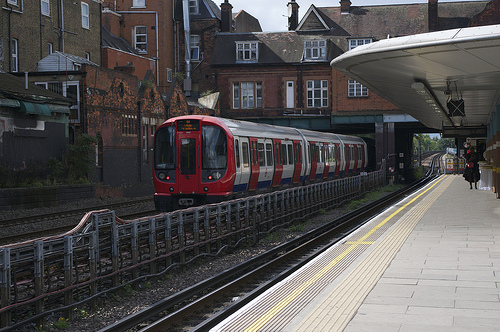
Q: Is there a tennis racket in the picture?
A: No, there are no rackets.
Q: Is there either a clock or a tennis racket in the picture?
A: No, there are no rackets or clocks.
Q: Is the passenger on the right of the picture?
A: Yes, the passenger is on the right of the image.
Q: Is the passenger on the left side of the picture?
A: No, the passenger is on the right of the image.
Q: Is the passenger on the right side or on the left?
A: The passenger is on the right of the image.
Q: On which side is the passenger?
A: The passenger is on the right of the image.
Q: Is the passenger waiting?
A: Yes, the passenger is waiting.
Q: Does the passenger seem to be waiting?
A: Yes, the passenger is waiting.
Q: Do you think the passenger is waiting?
A: Yes, the passenger is waiting.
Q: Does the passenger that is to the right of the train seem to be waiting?
A: Yes, the passenger is waiting.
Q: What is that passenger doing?
A: The passenger is waiting.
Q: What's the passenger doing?
A: The passenger is waiting.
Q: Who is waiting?
A: The passenger is waiting.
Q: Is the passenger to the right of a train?
A: Yes, the passenger is to the right of a train.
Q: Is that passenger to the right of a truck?
A: No, the passenger is to the right of a train.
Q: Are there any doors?
A: Yes, there is a door.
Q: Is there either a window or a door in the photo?
A: Yes, there is a door.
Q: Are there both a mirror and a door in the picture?
A: No, there is a door but no mirrors.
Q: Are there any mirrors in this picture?
A: No, there are no mirrors.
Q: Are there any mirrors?
A: No, there are no mirrors.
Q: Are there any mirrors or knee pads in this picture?
A: No, there are no mirrors or knee pads.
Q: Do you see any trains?
A: Yes, there is a train.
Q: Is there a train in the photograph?
A: Yes, there is a train.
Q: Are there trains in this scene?
A: Yes, there is a train.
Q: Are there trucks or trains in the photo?
A: Yes, there is a train.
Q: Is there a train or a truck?
A: Yes, there is a train.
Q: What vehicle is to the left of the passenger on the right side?
A: The vehicle is a train.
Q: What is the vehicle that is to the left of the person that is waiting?
A: The vehicle is a train.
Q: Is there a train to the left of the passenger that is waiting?
A: Yes, there is a train to the left of the passenger.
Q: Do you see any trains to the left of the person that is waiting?
A: Yes, there is a train to the left of the passenger.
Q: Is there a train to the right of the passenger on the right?
A: No, the train is to the left of the passenger.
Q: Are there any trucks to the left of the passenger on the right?
A: No, there is a train to the left of the passenger.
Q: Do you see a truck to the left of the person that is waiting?
A: No, there is a train to the left of the passenger.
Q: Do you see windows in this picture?
A: Yes, there is a window.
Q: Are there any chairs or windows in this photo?
A: Yes, there is a window.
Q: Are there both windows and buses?
A: No, there is a window but no buses.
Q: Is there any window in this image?
A: Yes, there is a window.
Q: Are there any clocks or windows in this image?
A: Yes, there is a window.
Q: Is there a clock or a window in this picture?
A: Yes, there is a window.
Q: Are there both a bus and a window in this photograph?
A: No, there is a window but no buses.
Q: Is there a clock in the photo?
A: No, there are no clocks.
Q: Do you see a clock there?
A: No, there are no clocks.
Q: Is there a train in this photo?
A: Yes, there is a train.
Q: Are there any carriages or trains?
A: Yes, there is a train.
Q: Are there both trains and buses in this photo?
A: No, there is a train but no buses.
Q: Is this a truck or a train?
A: This is a train.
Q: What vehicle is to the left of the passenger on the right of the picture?
A: The vehicle is a train.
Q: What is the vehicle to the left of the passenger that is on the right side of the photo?
A: The vehicle is a train.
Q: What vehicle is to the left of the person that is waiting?
A: The vehicle is a train.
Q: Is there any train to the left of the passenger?
A: Yes, there is a train to the left of the passenger.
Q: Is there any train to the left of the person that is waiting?
A: Yes, there is a train to the left of the passenger.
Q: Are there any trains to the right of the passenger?
A: No, the train is to the left of the passenger.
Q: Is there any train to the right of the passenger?
A: No, the train is to the left of the passenger.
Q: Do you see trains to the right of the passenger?
A: No, the train is to the left of the passenger.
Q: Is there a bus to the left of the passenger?
A: No, there is a train to the left of the passenger.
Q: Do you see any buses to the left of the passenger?
A: No, there is a train to the left of the passenger.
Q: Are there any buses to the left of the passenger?
A: No, there is a train to the left of the passenger.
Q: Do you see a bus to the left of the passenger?
A: No, there is a train to the left of the passenger.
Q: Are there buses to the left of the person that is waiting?
A: No, there is a train to the left of the passenger.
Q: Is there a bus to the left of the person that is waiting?
A: No, there is a train to the left of the passenger.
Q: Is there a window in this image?
A: Yes, there is a window.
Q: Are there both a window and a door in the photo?
A: Yes, there are both a window and a door.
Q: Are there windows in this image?
A: Yes, there is a window.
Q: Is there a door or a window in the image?
A: Yes, there is a window.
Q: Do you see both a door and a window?
A: Yes, there are both a window and a door.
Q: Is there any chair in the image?
A: No, there are no chairs.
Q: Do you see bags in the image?
A: No, there are no bags.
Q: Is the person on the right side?
A: Yes, the person is on the right of the image.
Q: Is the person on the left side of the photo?
A: No, the person is on the right of the image.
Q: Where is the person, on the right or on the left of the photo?
A: The person is on the right of the image.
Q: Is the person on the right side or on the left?
A: The person is on the right of the image.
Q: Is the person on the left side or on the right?
A: The person is on the right of the image.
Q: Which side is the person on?
A: The person is on the right of the image.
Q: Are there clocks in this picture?
A: No, there are no clocks.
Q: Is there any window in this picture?
A: Yes, there is a window.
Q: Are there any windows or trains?
A: Yes, there is a window.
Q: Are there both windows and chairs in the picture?
A: No, there is a window but no chairs.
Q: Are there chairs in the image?
A: No, there are no chairs.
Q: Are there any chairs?
A: No, there are no chairs.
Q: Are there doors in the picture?
A: Yes, there are doors.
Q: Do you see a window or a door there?
A: Yes, there are doors.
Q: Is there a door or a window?
A: Yes, there are doors.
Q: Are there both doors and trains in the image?
A: Yes, there are both doors and a train.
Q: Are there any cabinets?
A: No, there are no cabinets.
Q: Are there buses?
A: No, there are no buses.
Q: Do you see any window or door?
A: Yes, there is a window.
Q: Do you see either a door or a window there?
A: Yes, there is a window.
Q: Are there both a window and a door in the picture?
A: Yes, there are both a window and a door.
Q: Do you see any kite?
A: No, there are no kites.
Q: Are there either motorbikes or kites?
A: No, there are no kites or motorbikes.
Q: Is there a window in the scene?
A: Yes, there is a window.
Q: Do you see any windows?
A: Yes, there is a window.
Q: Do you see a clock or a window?
A: Yes, there is a window.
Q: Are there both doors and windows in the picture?
A: Yes, there are both a window and a door.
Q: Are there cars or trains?
A: Yes, there is a train.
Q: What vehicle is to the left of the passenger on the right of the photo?
A: The vehicle is a train.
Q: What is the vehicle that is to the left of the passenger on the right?
A: The vehicle is a train.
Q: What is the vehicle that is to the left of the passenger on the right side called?
A: The vehicle is a train.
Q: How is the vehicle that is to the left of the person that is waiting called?
A: The vehicle is a train.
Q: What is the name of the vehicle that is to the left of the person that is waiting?
A: The vehicle is a train.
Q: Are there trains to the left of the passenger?
A: Yes, there is a train to the left of the passenger.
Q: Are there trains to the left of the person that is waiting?
A: Yes, there is a train to the left of the passenger.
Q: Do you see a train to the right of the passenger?
A: No, the train is to the left of the passenger.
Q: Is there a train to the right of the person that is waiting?
A: No, the train is to the left of the passenger.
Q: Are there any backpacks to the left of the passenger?
A: No, there is a train to the left of the passenger.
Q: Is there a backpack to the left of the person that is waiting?
A: No, there is a train to the left of the passenger.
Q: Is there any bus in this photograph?
A: No, there are no buses.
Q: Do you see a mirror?
A: No, there are no mirrors.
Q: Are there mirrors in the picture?
A: No, there are no mirrors.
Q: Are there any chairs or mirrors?
A: No, there are no mirrors or chairs.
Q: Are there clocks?
A: No, there are no clocks.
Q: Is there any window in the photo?
A: Yes, there is a window.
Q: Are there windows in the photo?
A: Yes, there is a window.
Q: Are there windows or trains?
A: Yes, there is a window.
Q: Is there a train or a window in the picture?
A: Yes, there is a window.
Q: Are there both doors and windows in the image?
A: Yes, there are both a window and a door.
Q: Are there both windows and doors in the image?
A: Yes, there are both a window and a door.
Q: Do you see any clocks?
A: No, there are no clocks.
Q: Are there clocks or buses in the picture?
A: No, there are no clocks or buses.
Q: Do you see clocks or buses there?
A: No, there are no clocks or buses.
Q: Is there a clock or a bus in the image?
A: No, there are no clocks or buses.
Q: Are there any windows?
A: Yes, there is a window.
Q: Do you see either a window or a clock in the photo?
A: Yes, there is a window.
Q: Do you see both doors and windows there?
A: Yes, there are both a window and a door.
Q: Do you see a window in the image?
A: Yes, there is a window.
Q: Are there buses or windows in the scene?
A: Yes, there is a window.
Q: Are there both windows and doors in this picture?
A: Yes, there are both a window and a door.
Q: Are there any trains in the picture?
A: Yes, there is a train.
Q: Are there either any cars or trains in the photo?
A: Yes, there is a train.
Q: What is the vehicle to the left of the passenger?
A: The vehicle is a train.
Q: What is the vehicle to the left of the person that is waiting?
A: The vehicle is a train.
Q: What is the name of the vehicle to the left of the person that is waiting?
A: The vehicle is a train.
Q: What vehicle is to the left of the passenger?
A: The vehicle is a train.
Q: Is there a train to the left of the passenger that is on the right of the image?
A: Yes, there is a train to the left of the passenger.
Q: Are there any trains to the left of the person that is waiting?
A: Yes, there is a train to the left of the passenger.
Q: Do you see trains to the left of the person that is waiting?
A: Yes, there is a train to the left of the passenger.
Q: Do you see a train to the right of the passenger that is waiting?
A: No, the train is to the left of the passenger.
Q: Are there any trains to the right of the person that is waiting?
A: No, the train is to the left of the passenger.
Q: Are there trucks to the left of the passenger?
A: No, there is a train to the left of the passenger.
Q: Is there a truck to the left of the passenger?
A: No, there is a train to the left of the passenger.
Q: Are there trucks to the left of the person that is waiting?
A: No, there is a train to the left of the passenger.